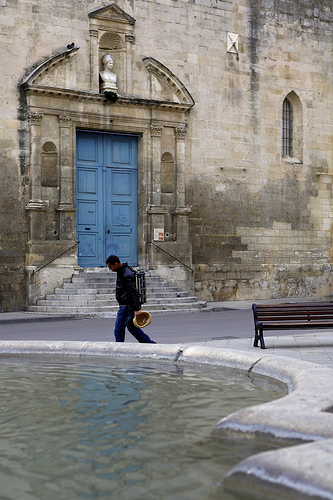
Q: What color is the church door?
A: Blue.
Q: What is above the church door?
A: A bust.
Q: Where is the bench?
A: By the fountain.